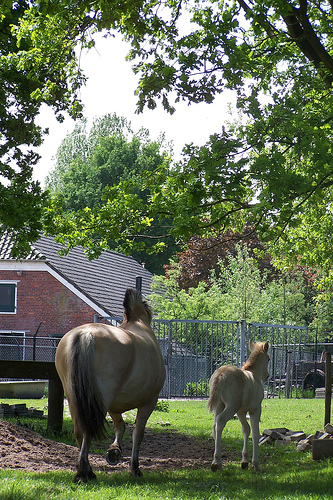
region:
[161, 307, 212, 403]
the gate is gray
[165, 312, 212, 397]
the gate is gray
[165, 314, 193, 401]
the gate is gray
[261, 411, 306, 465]
bricks on the ground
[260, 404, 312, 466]
bricks on the ground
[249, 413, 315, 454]
bricks on the ground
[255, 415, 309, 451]
bricks on the ground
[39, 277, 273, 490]
An adult horse and baby horse gracing through a farm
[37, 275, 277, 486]
An adult horse and baby horse gracing through a farm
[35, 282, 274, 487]
An adult horse and baby horse gracing through a farm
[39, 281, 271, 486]
An adult horse and baby horse gracing through a farm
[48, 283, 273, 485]
An adult horse and baby horse gracing through a farm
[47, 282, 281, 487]
An adult horse and baby horse gracing through a farm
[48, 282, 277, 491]
An adult horse and baby horse gracing through a farm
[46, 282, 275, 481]
An adult horse and baby horse gracing through a farm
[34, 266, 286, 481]
There is a young horse running in front of an older horse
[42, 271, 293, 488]
There is an older horse running behind a younger horse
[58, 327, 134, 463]
The horse's tail is black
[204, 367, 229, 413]
The young horse's tail is brown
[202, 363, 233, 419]
The young horse's tail is short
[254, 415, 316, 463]
There is a pile of rocks in front of the young horse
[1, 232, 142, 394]
The barn is red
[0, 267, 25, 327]
The barn windows have white trim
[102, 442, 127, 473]
The horse has shoes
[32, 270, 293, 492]
horses side by side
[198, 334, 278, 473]
smaller horse on ground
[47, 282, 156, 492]
large horse on ground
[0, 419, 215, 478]
pile of dirt on ground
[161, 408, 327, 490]
lawn with green grass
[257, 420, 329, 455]
concrete blocks on ground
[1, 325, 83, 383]
fence near the home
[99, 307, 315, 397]
enclosed area near home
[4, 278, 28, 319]
window in the home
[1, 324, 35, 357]
window in the home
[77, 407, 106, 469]
leg of a horse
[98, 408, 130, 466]
leg of a horse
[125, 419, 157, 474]
leg of a horse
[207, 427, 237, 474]
leg of a horse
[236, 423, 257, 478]
leg of a horse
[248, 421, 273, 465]
leg of a horse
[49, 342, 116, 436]
tail of a horse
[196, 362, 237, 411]
tail of a horse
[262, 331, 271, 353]
ear of a horse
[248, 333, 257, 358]
ear of a horse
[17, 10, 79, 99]
the leaves are green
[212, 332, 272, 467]
the foal is brown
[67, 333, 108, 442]
tail hair is long, grey and black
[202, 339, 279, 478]
a horse in the grass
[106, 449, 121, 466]
horseshoe on hoof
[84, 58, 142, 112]
sky above the land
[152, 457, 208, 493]
shadow on the ground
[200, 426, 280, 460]
legs of the animal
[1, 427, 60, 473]
dirt on the ground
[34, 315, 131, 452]
tail of the horse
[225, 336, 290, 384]
head of the horse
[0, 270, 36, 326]
window on a building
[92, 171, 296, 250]
leaves on the tree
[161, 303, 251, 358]
fence near the animals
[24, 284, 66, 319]
red bricks on the building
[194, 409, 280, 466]
legs on the horse